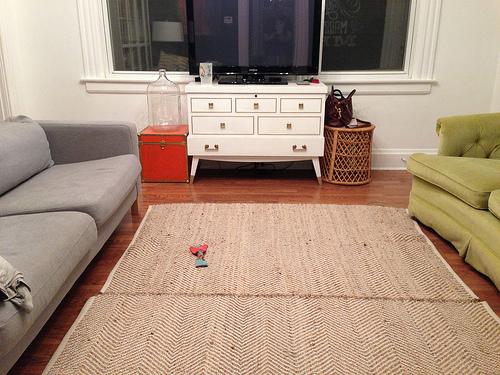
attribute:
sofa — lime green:
[407, 100, 498, 272]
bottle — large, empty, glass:
[147, 69, 183, 132]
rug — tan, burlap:
[101, 201, 480, 301]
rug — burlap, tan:
[40, 291, 499, 373]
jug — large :
[141, 67, 186, 134]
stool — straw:
[325, 122, 375, 182]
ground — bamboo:
[373, 142, 454, 207]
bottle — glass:
[131, 72, 195, 133]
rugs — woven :
[35, 202, 498, 373]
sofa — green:
[398, 104, 499, 295]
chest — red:
[110, 109, 235, 197]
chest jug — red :
[136, 67, 190, 184]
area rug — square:
[38, 202, 496, 372]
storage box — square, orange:
[141, 121, 192, 185]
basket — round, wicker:
[323, 119, 376, 184]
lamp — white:
[151, 18, 183, 42]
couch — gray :
[8, 69, 150, 356]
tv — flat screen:
[187, 0, 321, 82]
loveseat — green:
[406, 112, 499, 293]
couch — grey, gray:
[0, 112, 144, 373]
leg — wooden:
[131, 192, 138, 216]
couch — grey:
[32, 132, 120, 325]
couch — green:
[404, 111, 498, 290]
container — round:
[320, 120, 376, 184]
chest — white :
[139, 124, 190, 183]